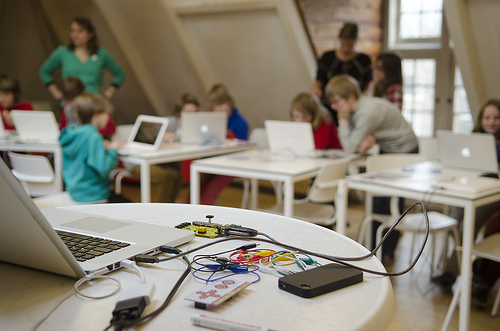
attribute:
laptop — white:
[119, 112, 168, 155]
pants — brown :
[137, 166, 182, 203]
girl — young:
[45, 14, 110, 81]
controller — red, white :
[187, 275, 249, 311]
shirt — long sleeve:
[34, 44, 119, 109]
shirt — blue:
[58, 121, 118, 201]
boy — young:
[56, 88, 119, 203]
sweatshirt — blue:
[59, 121, 122, 202]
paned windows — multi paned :
[392, 3, 476, 133]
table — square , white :
[184, 140, 348, 222]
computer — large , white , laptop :
[110, 97, 179, 172]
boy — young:
[326, 76, 437, 174]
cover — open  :
[0, 152, 85, 276]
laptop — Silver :
[0, 150, 200, 284]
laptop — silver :
[3, 156, 201, 298]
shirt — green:
[64, 125, 114, 200]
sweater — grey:
[335, 95, 417, 154]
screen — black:
[132, 120, 162, 144]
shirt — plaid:
[378, 82, 404, 115]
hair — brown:
[372, 50, 402, 97]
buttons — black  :
[51, 221, 132, 261]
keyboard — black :
[50, 227, 130, 261]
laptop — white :
[120, 102, 173, 163]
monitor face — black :
[130, 119, 165, 144]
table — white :
[0, 192, 398, 330]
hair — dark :
[60, 13, 105, 63]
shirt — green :
[27, 39, 127, 100]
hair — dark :
[323, 22, 364, 58]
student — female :
[365, 38, 409, 118]